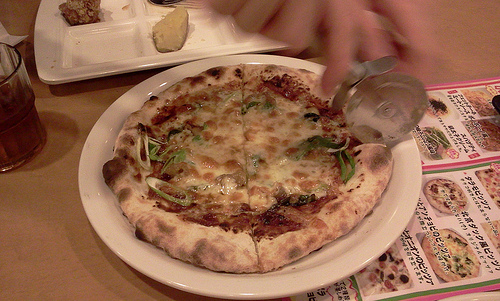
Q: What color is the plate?
A: White.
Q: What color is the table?
A: Brown.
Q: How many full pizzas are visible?
A: One.